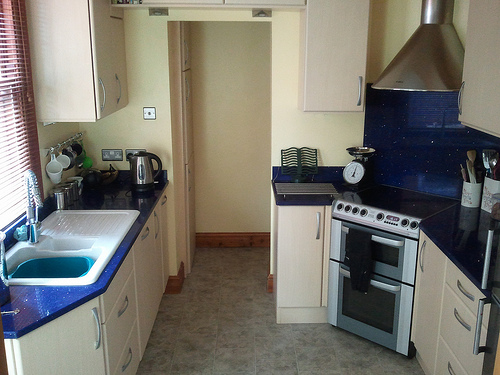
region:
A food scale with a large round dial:
[341, 144, 375, 188]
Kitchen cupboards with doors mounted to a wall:
[23, 0, 128, 123]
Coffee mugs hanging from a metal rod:
[42, 130, 84, 185]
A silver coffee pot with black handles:
[125, 149, 162, 191]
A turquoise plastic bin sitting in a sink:
[3, 242, 121, 287]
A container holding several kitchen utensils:
[458, 148, 482, 209]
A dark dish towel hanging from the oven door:
[343, 225, 378, 293]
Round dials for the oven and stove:
[334, 202, 419, 232]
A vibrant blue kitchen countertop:
[0, 169, 167, 339]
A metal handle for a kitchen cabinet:
[90, 305, 102, 352]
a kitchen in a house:
[20, 116, 497, 371]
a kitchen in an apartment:
[2, 102, 491, 373]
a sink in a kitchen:
[2, 166, 137, 308]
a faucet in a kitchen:
[18, 160, 45, 240]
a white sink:
[3, 182, 137, 293]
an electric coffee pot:
[124, 144, 169, 197]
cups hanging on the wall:
[37, 136, 101, 187]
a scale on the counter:
[340, 138, 376, 197]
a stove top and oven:
[324, 171, 419, 360]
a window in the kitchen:
[0, 3, 49, 228]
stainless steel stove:
[305, 177, 447, 374]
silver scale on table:
[342, 140, 384, 192]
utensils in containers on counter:
[445, 136, 499, 221]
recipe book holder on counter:
[270, 140, 330, 183]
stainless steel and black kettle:
[112, 142, 166, 215]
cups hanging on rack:
[36, 130, 101, 188]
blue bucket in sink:
[2, 245, 106, 299]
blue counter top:
[4, 285, 105, 350]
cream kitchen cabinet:
[274, 199, 343, 339]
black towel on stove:
[330, 220, 391, 307]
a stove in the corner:
[323, 182, 423, 357]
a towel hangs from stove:
[333, 212, 400, 301]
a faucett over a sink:
[16, 163, 56, 246]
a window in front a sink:
[0, 4, 141, 303]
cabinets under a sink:
[13, 214, 183, 374]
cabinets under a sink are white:
[33, 210, 189, 372]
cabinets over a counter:
[24, 0, 152, 126]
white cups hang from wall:
[37, 141, 76, 188]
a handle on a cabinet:
[87, 297, 107, 352]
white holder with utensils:
[452, 137, 497, 214]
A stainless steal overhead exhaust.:
[375, 23, 472, 102]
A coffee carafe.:
[122, 145, 168, 195]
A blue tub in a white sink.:
[7, 248, 100, 290]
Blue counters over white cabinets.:
[10, 281, 76, 366]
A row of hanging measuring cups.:
[42, 128, 89, 185]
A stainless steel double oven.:
[322, 192, 424, 357]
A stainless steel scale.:
[333, 143, 378, 190]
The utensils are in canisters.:
[455, 142, 497, 212]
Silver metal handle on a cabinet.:
[276, 200, 327, 311]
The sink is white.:
[4, 202, 135, 287]